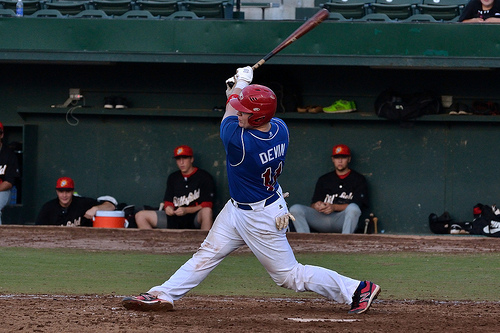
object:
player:
[119, 63, 381, 315]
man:
[291, 144, 370, 233]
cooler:
[91, 210, 125, 228]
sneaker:
[323, 99, 354, 114]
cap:
[173, 146, 193, 158]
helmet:
[230, 83, 276, 127]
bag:
[375, 83, 442, 121]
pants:
[146, 186, 359, 304]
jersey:
[219, 115, 290, 204]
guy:
[36, 176, 116, 225]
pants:
[290, 203, 362, 234]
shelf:
[15, 105, 497, 120]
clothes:
[470, 200, 500, 235]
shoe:
[347, 278, 380, 315]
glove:
[234, 66, 256, 85]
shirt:
[165, 167, 212, 209]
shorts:
[156, 210, 202, 229]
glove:
[276, 211, 296, 230]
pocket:
[274, 210, 292, 235]